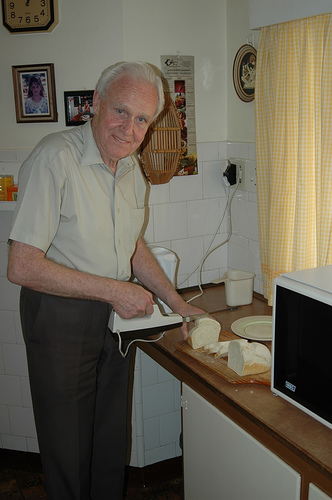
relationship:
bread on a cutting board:
[221, 334, 283, 384] [186, 327, 270, 398]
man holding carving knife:
[13, 29, 200, 346] [108, 293, 208, 334]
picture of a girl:
[8, 58, 65, 129] [26, 76, 46, 101]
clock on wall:
[1, 3, 67, 41] [98, 11, 180, 44]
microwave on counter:
[266, 250, 330, 423] [149, 273, 323, 419]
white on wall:
[184, 199, 221, 232] [98, 11, 180, 44]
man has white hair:
[13, 29, 200, 346] [99, 65, 165, 86]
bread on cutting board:
[221, 334, 283, 384] [186, 327, 270, 398]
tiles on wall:
[163, 204, 231, 240] [98, 11, 180, 44]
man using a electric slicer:
[13, 29, 200, 346] [106, 282, 208, 350]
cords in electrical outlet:
[202, 203, 240, 237] [226, 158, 239, 182]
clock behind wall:
[1, 3, 67, 41] [98, 11, 180, 44]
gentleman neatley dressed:
[13, 29, 200, 346] [41, 164, 129, 489]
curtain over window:
[256, 30, 327, 122] [243, 14, 329, 281]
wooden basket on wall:
[125, 88, 185, 189] [98, 11, 180, 44]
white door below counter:
[184, 199, 221, 232] [149, 273, 323, 419]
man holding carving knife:
[13, 29, 200, 346] [106, 282, 208, 350]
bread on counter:
[221, 334, 283, 384] [149, 273, 323, 419]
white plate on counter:
[233, 306, 273, 349] [149, 273, 323, 419]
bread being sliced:
[221, 334, 283, 384] [174, 310, 225, 328]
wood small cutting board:
[206, 360, 225, 378] [186, 327, 270, 398]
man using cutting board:
[13, 29, 200, 346] [186, 327, 270, 398]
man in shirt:
[13, 29, 200, 346] [10, 132, 163, 290]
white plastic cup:
[184, 199, 221, 232] [206, 256, 262, 311]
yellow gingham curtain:
[267, 51, 294, 79] [256, 30, 327, 122]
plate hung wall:
[226, 35, 268, 108] [98, 11, 180, 44]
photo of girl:
[8, 58, 65, 129] [26, 76, 46, 101]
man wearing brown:
[13, 29, 200, 346] [10, 274, 137, 498]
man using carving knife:
[13, 29, 200, 346] [108, 293, 208, 334]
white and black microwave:
[184, 199, 221, 232] [266, 250, 330, 423]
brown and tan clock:
[10, 274, 137, 498] [1, 3, 67, 41]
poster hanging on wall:
[156, 43, 214, 169] [98, 11, 180, 44]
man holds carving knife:
[13, 29, 200, 346] [108, 293, 208, 334]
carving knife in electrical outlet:
[108, 293, 208, 334] [213, 149, 260, 190]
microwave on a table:
[266, 250, 330, 423] [215, 327, 272, 414]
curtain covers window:
[256, 30, 327, 122] [243, 14, 329, 281]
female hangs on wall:
[8, 58, 65, 129] [98, 11, 180, 44]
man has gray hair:
[13, 29, 200, 346] [89, 64, 166, 98]